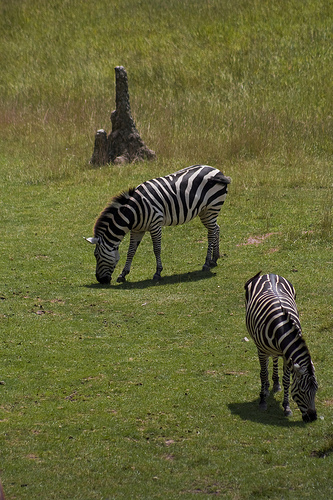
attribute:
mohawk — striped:
[89, 183, 139, 245]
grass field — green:
[13, 319, 148, 386]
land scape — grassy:
[1, 3, 328, 494]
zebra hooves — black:
[245, 375, 296, 437]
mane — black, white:
[85, 191, 139, 215]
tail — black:
[209, 172, 232, 184]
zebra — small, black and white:
[84, 165, 233, 284]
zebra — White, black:
[73, 167, 249, 307]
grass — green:
[57, 321, 140, 406]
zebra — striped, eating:
[52, 180, 257, 278]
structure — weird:
[90, 62, 157, 166]